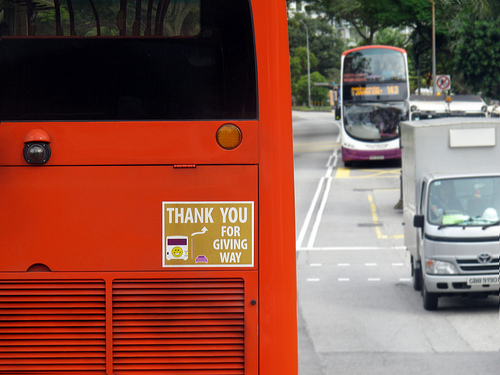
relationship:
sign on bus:
[150, 187, 262, 277] [3, 4, 311, 375]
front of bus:
[335, 42, 411, 161] [315, 35, 420, 173]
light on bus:
[339, 68, 408, 105] [315, 35, 420, 173]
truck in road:
[389, 109, 499, 310] [298, 111, 499, 374]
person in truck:
[431, 188, 462, 225] [389, 109, 499, 310]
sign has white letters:
[150, 187, 262, 277] [166, 206, 250, 228]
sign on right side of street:
[429, 70, 458, 94] [359, 9, 499, 322]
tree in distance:
[291, 14, 334, 113] [293, 3, 496, 137]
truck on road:
[389, 109, 499, 310] [298, 111, 499, 374]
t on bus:
[160, 199, 177, 229] [3, 4, 311, 375]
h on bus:
[169, 200, 184, 229] [3, 4, 311, 375]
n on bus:
[193, 202, 205, 227] [3, 4, 311, 375]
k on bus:
[203, 198, 217, 225] [3, 4, 311, 375]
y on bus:
[217, 202, 231, 225] [3, 4, 311, 375]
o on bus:
[227, 202, 237, 227] [3, 4, 311, 375]